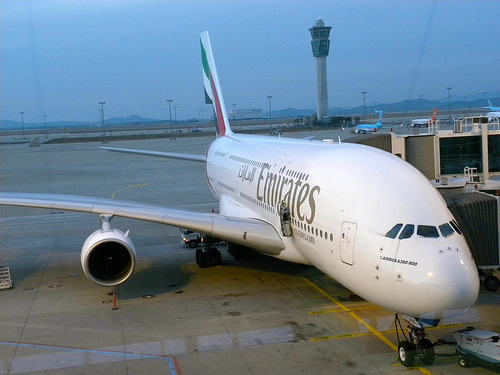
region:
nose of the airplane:
[443, 268, 478, 310]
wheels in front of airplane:
[392, 336, 433, 373]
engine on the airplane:
[82, 235, 149, 296]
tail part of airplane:
[188, 33, 234, 132]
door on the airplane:
[335, 219, 360, 282]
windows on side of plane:
[299, 220, 330, 245]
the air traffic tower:
[307, 20, 339, 97]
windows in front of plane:
[406, 226, 460, 239]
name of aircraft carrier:
[261, 162, 313, 215]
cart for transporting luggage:
[451, 322, 497, 362]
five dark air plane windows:
[382, 210, 479, 264]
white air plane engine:
[72, 203, 159, 305]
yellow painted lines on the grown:
[295, 270, 386, 358]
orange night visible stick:
[108, 291, 126, 318]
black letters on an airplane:
[234, 152, 356, 246]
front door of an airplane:
[336, 213, 361, 277]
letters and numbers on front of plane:
[379, 249, 425, 276]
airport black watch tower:
[303, 12, 346, 124]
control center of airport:
[301, 14, 352, 115]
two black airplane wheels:
[387, 309, 437, 371]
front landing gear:
[370, 298, 457, 373]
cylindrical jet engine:
[51, 190, 169, 309]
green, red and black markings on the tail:
[180, 17, 263, 168]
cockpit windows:
[370, 177, 482, 262]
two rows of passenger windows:
[183, 142, 357, 252]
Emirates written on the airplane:
[242, 157, 333, 236]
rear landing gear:
[170, 207, 248, 295]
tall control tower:
[292, 11, 347, 138]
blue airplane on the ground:
[328, 97, 398, 145]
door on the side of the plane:
[321, 205, 378, 292]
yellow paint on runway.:
[350, 319, 380, 339]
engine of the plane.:
[72, 237, 132, 297]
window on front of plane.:
[419, 226, 436, 237]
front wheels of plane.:
[399, 339, 435, 364]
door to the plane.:
[332, 218, 353, 263]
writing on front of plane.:
[377, 256, 417, 267]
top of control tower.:
[303, 15, 335, 61]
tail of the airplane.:
[201, 42, 230, 131]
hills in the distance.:
[108, 112, 145, 123]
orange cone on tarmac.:
[104, 292, 126, 310]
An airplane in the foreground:
[3, 18, 499, 360]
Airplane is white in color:
[0, 26, 499, 361]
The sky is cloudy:
[3, 0, 498, 130]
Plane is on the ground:
[4, 21, 492, 373]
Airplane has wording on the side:
[236, 153, 331, 227]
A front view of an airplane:
[326, 169, 493, 337]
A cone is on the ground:
[101, 286, 136, 323]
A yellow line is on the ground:
[292, 266, 433, 374]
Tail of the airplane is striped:
[190, 31, 244, 145]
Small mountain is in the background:
[83, 83, 165, 128]